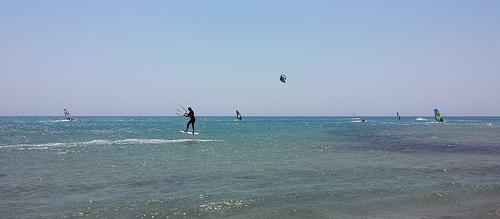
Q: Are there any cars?
A: No, there are no cars.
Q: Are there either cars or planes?
A: No, there are no cars or planes.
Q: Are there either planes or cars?
A: No, there are no cars or planes.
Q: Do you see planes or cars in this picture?
A: No, there are no cars or planes.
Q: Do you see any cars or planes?
A: No, there are no cars or planes.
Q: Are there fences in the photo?
A: No, there are no fences.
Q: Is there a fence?
A: No, there are no fences.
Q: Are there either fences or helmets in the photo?
A: No, there are no fences or helmets.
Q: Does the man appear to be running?
A: Yes, the man is running.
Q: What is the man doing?
A: The man is running.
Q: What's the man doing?
A: The man is running.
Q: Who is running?
A: The man is running.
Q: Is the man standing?
A: No, the man is running.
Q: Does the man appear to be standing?
A: No, the man is running.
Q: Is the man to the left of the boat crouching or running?
A: The man is running.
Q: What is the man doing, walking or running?
A: The man is running.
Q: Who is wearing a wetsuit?
A: The man is wearing a wetsuit.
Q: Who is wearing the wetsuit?
A: The man is wearing a wetsuit.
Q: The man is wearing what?
A: The man is wearing a wetsuit.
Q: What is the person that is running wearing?
A: The man is wearing a wetsuit.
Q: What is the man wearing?
A: The man is wearing a wetsuit.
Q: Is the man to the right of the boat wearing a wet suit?
A: Yes, the man is wearing a wet suit.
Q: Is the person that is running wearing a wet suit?
A: Yes, the man is wearing a wet suit.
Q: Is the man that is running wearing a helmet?
A: No, the man is wearing a wet suit.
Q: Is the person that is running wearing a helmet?
A: No, the man is wearing a wet suit.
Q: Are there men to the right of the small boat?
A: Yes, there is a man to the right of the boat.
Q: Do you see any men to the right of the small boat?
A: Yes, there is a man to the right of the boat.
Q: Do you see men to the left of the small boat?
A: No, the man is to the right of the boat.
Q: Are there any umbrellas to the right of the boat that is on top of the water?
A: No, there is a man to the right of the boat.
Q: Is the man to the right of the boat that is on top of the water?
A: Yes, the man is to the right of the boat.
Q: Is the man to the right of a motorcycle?
A: No, the man is to the right of the boat.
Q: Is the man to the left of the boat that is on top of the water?
A: No, the man is to the right of the boat.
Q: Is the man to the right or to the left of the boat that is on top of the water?
A: The man is to the right of the boat.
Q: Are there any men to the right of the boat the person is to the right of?
A: No, the man is to the left of the boat.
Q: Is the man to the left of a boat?
A: Yes, the man is to the left of a boat.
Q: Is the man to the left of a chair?
A: No, the man is to the left of a boat.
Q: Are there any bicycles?
A: No, there are no bicycles.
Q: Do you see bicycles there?
A: No, there are no bicycles.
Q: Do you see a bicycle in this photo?
A: No, there are no bicycles.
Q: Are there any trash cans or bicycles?
A: No, there are no bicycles or trash cans.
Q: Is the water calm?
A: Yes, the water is calm.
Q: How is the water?
A: The water is calm.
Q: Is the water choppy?
A: No, the water is calm.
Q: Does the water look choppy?
A: No, the water is calm.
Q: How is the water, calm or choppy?
A: The water is calm.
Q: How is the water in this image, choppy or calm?
A: The water is calm.